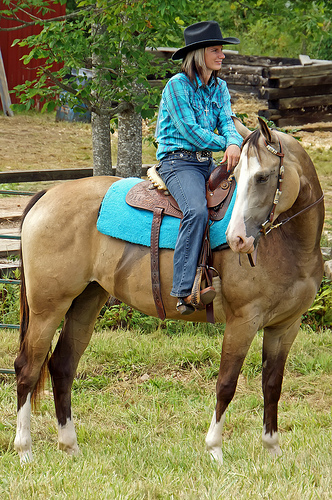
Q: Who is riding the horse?
A: The woman.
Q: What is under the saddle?
A: A blue blanket.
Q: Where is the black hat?
A: On the woman's head.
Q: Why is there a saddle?
A: To allow the woman ride.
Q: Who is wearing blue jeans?
A: The woman.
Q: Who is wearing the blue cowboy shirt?
A: The woman.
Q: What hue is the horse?
A: Beige.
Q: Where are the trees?
A: Behind the horse.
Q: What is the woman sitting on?
A: A horse.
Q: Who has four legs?
A: Horse.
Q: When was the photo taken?
A: During daytime.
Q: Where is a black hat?
A: On lady's head.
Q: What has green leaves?
A: A tree.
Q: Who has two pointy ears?
A: The horse.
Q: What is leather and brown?
A: Saddle.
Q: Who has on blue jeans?
A: The lady.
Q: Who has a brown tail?
A: A horse.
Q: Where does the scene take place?
A: At a ranch.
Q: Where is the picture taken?
A: A ranch.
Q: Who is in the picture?
A: A woman.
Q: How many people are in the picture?
A: One.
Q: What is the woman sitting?
A: On a horse.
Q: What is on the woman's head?
A: A hat.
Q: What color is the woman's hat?
A: Black.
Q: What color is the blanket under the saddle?
A: Blue.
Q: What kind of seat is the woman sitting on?
A: Saddle.